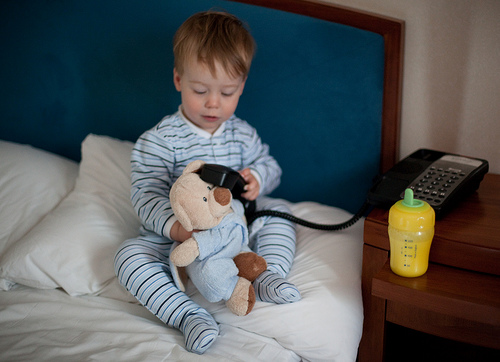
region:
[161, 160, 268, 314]
a small teddy bear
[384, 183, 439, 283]
a yellow juice cup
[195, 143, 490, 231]
a black phone on a table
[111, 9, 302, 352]
a boy with a phone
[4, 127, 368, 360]
a white pillow on a bed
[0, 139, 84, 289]
a white pillow on a bed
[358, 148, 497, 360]
a wooden table by the bed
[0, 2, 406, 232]
a blue head rest for a bed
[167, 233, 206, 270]
the arm of a teddy bear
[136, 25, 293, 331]
a kid sitting on a bed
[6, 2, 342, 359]
a bed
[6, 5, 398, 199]
the headboard on the bed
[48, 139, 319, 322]
a pillow on the bed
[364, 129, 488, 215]
a black phone on a table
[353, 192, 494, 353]
a wooden desk next to the bed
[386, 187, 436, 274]
a yellow cup on the table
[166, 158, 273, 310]
a stuffed animal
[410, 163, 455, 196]
dials on the phone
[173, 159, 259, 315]
A boy holding a teddy bear.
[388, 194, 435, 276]
Milk in a sippy cup.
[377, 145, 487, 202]
Black home phone.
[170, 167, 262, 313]
Brown teddy bear in blue outfit.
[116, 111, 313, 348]
The boy wearing blue striped pajamas.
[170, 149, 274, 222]
Boy putting the phone on teddy bear's ear.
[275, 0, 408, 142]
Blue and brown headboard.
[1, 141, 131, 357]
White sheet and pillows.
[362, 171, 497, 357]
Dark brown night stand.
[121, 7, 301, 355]
Boy playing with his teddy bear.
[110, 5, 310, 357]
Young boy holding a phone to a stuffed animal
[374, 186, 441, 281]
Yellow sippy cup with a green lid top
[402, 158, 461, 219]
Base keypad of a phone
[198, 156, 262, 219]
Black telephone being held by a kid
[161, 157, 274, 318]
Stuff bear being held by a young boy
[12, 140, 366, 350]
White pillow being sat on by a kid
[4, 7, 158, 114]
Blue background on the headboard of a bed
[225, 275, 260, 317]
The foot of a stuffed bear being held by boy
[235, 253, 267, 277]
The foot of a stuffed bear being held by boy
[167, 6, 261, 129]
The head of a young boy